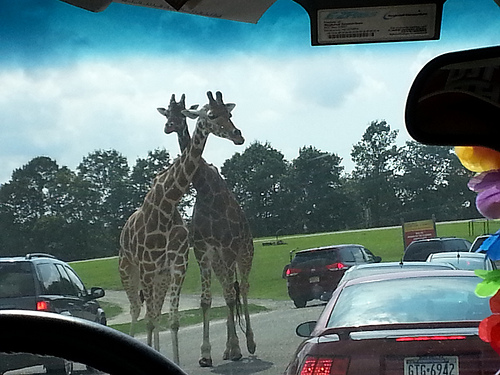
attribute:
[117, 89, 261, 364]
giraffes — male, female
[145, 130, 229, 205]
necks — crossed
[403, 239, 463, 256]
car — careful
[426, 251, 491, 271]
car — careful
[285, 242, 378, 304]
car — careful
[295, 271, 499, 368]
car — careful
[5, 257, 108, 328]
car — careful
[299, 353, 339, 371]
light — red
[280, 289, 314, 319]
wheel — black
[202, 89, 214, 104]
horns — brown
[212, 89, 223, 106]
horns — brown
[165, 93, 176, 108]
horns — brown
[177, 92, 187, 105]
horns — brown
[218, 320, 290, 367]
road — busy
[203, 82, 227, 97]
horns — brown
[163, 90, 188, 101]
horns — brown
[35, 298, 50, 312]
light — brake light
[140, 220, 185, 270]
spots — brown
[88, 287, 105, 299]
mirror — side view mirror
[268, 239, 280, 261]
grass — green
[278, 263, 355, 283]
lights — parking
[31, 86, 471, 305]
reserve — game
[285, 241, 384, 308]
car — black